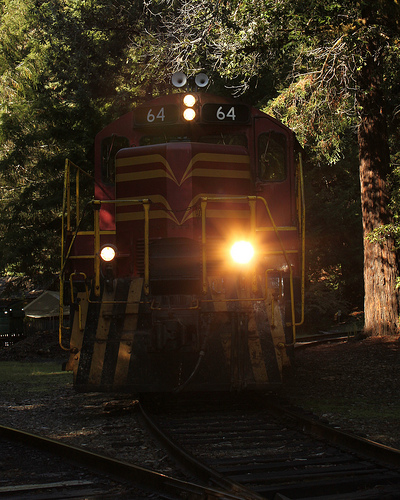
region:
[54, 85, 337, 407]
this is a train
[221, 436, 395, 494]
this is a railway train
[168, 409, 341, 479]
this is a railway train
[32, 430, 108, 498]
this is a railway train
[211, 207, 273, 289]
the light on a train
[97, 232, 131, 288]
the light on a train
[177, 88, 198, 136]
the light on a train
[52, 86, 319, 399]
train is passing by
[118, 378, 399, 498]
couple train railings on floor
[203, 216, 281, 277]
head lights from a moving train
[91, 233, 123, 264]
lights from moving train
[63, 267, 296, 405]
the bottom bumper of train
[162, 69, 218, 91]
sound horn from train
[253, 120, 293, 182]
front windshield of train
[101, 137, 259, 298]
front engine of train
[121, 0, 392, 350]
a tall tree with stems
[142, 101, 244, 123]
numbers en-printed on train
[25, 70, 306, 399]
a large train engine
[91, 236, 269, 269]
head lights on a train car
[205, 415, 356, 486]
a set of train tracks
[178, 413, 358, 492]
a set of railroad trecks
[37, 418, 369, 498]
two sets of train tracks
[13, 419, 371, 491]
two sets of rail road tracks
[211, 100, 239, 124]
white numbers painted on a train car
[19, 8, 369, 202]
a train under several trees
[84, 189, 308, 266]
a yellow hand rail on a train car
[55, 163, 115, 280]
a set of steps on a train car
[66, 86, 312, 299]
four head lights on train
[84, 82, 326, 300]
the headlights are turned on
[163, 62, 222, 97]
two horns on top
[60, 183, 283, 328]
a yellow railing on train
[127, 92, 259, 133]
two white numbers on black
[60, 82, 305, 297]
a red and yellow train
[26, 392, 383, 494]
empty track in front of train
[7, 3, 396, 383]
large trees around train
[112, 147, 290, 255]
yellow lines on train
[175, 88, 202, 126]
two top headlights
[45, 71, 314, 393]
train on the track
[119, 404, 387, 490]
track train is traveling on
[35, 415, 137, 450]
rocks and gravel between tracks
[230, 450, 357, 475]
planks on the tracks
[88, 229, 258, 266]
lights on the train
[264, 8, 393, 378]
tree next to tracks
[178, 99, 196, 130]
lights on the train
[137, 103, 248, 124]
numbers on the train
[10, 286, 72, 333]
building behind the train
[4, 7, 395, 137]
tree tops behind train